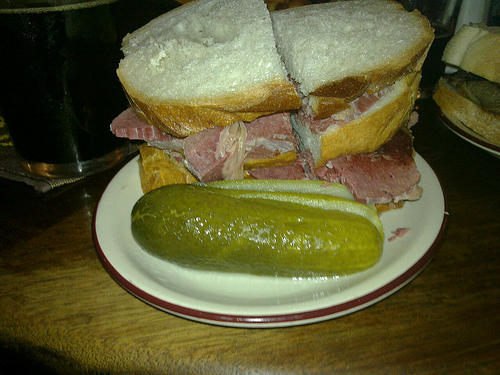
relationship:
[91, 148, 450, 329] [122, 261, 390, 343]
lunch plate with a stripe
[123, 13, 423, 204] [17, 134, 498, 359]
sandwich on table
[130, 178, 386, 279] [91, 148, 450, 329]
dill pickle on lunch plate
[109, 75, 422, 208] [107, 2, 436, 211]
meat on a sandwich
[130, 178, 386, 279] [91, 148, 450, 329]
dill pickle on a lunch plate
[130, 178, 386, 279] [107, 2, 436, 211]
dill pickle next to sandwich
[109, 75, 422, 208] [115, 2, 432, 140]
meat on bread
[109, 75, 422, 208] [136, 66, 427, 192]
meat on bread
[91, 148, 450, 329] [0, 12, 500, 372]
lunch plate on table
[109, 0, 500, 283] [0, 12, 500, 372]
food on table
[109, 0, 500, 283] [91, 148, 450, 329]
food on lunch plate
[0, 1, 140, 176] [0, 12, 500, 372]
drink on table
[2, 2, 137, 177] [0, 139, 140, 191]
glass on coaster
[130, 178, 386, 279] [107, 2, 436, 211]
dill pickle on sandwich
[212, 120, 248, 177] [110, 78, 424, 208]
fat on ham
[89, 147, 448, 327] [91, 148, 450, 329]
stripe on lunch plate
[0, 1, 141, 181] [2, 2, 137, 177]
drink in glass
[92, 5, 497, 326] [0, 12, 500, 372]
food on table